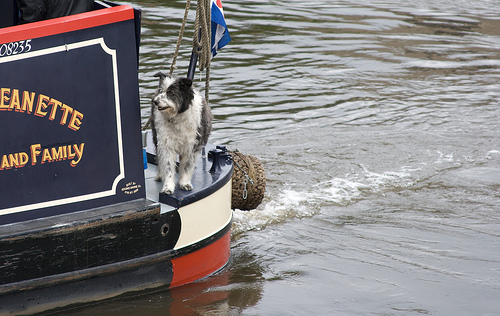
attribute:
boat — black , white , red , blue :
[0, 8, 237, 311]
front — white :
[161, 155, 252, 303]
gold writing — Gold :
[1, 73, 90, 191]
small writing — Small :
[120, 180, 144, 193]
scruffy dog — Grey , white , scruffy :
[149, 74, 214, 204]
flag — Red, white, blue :
[195, 0, 238, 56]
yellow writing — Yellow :
[1, 79, 91, 208]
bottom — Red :
[171, 218, 237, 294]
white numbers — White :
[1, 35, 44, 62]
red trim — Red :
[0, 8, 149, 38]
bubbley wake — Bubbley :
[237, 133, 496, 244]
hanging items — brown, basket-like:
[226, 141, 271, 217]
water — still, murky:
[74, 3, 497, 310]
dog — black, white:
[152, 69, 212, 197]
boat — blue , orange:
[0, 1, 267, 313]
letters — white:
[1, 39, 33, 57]